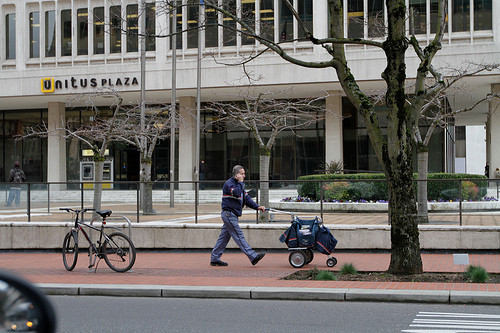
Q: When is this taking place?
A: Daytime.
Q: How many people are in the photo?
A: One.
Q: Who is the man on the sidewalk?
A: Mailman.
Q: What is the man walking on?
A: Sidewalk.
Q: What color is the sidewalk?
A: Red.